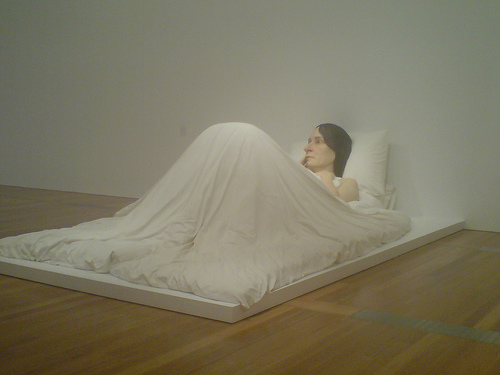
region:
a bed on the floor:
[112, 28, 364, 338]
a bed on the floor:
[143, 145, 281, 372]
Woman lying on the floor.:
[95, 82, 498, 279]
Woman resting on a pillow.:
[245, 60, 450, 270]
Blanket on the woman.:
[122, 78, 422, 300]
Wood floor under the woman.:
[375, 249, 453, 363]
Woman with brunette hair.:
[282, 84, 418, 211]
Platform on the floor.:
[42, 191, 278, 354]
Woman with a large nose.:
[278, 95, 417, 240]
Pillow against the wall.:
[270, 87, 458, 212]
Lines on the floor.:
[81, 280, 176, 371]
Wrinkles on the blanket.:
[139, 133, 284, 263]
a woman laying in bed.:
[60, 102, 372, 287]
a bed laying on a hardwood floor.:
[0, 120, 470, 324]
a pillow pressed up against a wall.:
[281, 121, 406, 201]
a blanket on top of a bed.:
[0, 122, 409, 301]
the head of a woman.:
[292, 120, 358, 185]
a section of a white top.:
[306, 173, 350, 188]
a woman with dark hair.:
[292, 110, 366, 184]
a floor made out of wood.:
[1, 186, 498, 373]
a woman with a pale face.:
[296, 110, 352, 173]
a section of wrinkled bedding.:
[234, 266, 314, 305]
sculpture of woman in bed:
[125, 109, 398, 279]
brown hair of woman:
[319, 116, 354, 176]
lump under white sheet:
[167, 111, 289, 238]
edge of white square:
[186, 277, 298, 337]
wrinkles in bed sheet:
[152, 185, 217, 256]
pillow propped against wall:
[352, 122, 390, 182]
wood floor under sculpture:
[73, 282, 254, 354]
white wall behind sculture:
[321, 85, 435, 207]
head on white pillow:
[337, 122, 369, 177]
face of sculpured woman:
[300, 127, 328, 168]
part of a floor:
[368, 297, 429, 354]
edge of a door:
[182, 279, 240, 346]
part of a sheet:
[213, 187, 263, 252]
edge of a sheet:
[189, 284, 231, 301]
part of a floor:
[316, 301, 386, 356]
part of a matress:
[217, 241, 275, 299]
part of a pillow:
[375, 180, 400, 200]